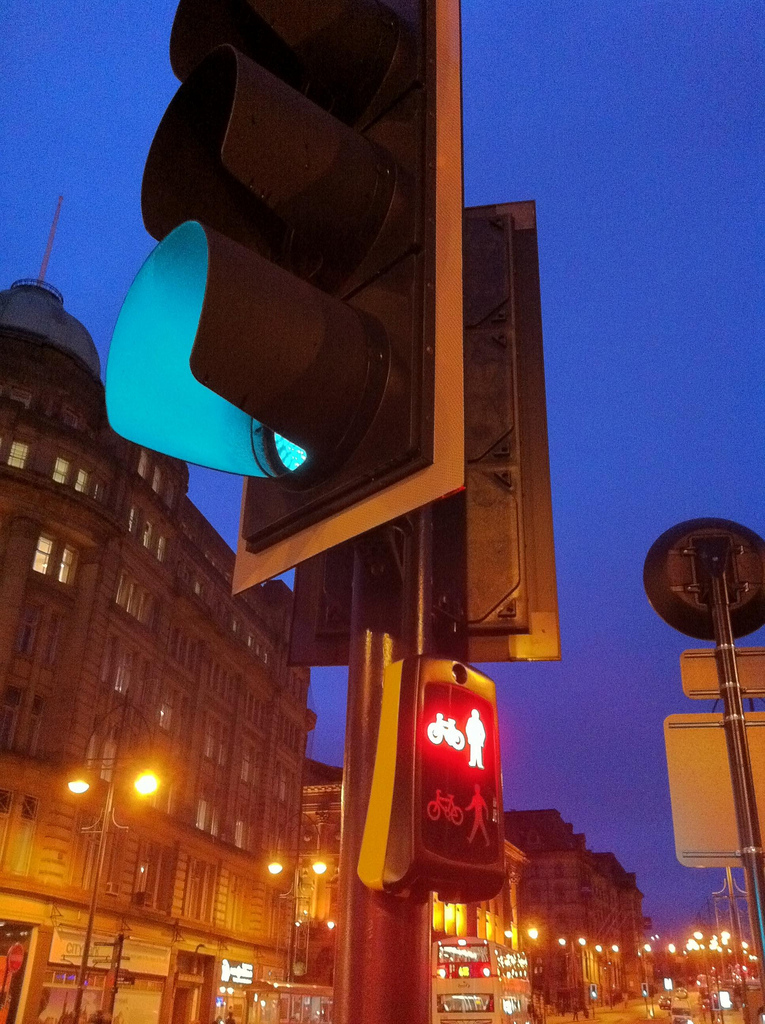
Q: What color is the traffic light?
A: Green.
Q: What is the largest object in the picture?
A: The traffic light.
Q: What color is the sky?
A: Blue.